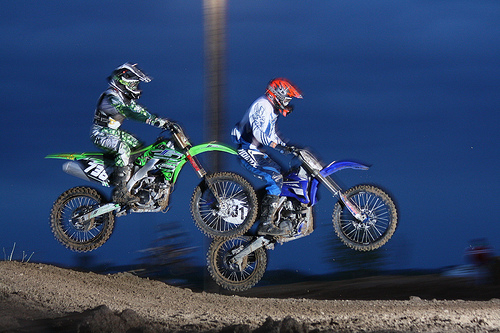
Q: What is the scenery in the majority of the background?
A: Sky.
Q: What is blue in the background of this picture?
A: Sky.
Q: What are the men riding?
A: Motorbikes.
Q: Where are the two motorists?
A: Above the dirt track.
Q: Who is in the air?
A: Motorbike riders.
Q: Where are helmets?
A: On rider's heads.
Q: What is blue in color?
A: The sky.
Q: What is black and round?
A: Tires.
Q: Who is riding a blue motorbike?
A: Rider on right.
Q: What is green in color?
A: Motorbike on left.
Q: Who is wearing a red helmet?
A: Rider on the right.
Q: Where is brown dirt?
A: On the ground.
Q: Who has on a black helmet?
A: Rider on left.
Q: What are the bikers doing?
A: Racing.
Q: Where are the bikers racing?
A: On a dirt track.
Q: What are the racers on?
A: Motorbikes.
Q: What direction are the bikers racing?
A: Right.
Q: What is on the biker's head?
A: A helmet.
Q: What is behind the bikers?
A: A pole.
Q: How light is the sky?
A: Almost dark.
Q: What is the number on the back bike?
A: 738.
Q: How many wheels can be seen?
A: 4.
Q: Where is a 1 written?
A: On a bike tire.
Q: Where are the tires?
A: In the air.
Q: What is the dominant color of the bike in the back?
A: Green.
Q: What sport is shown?
A: Motocross.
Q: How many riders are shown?
A: Two.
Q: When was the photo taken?
A: Night.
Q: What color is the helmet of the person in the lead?
A: Orange.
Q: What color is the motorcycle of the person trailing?
A: Green.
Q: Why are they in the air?
A: The jumped.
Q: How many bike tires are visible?
A: Four.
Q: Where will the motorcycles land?
A: On dirt.